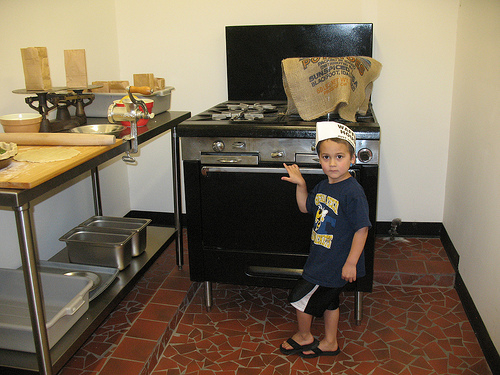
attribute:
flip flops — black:
[278, 323, 396, 373]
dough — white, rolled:
[4, 129, 119, 146]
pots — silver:
[78, 206, 151, 258]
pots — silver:
[55, 222, 137, 269]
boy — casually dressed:
[284, 100, 379, 360]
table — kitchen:
[1, 112, 190, 374]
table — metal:
[18, 61, 209, 293]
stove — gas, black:
[175, 98, 389, 308]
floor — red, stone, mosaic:
[180, 323, 265, 373]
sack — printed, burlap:
[277, 50, 379, 122]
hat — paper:
[314, 117, 356, 147]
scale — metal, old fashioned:
[11, 87, 103, 130]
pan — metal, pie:
[68, 122, 134, 136]